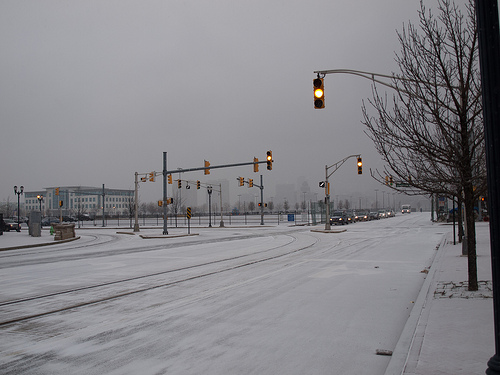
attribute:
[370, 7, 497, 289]
trees — Leafless 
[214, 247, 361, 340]
snow — White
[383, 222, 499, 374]
sidewalk — Snow coated 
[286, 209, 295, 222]
bin — Blue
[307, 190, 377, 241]
car — Stopped 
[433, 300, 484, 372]
snow — White 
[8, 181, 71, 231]
poles — tall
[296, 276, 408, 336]
snow — White 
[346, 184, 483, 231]
cars — Stalled 